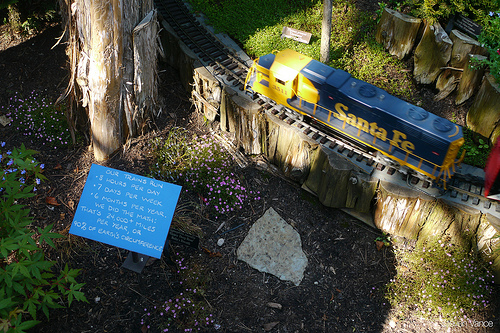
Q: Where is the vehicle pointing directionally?
A: Left.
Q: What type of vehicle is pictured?
A: Toy train.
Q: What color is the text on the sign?
A: White.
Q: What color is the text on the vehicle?
A: Yellow.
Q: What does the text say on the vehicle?
A: Santa Fe.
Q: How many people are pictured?
A: None.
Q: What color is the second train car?
A: Red.